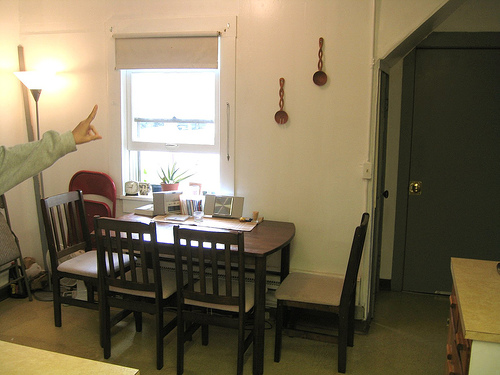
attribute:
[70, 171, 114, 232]
chair — folding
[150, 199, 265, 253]
table top — cluttered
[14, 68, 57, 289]
lamp — lit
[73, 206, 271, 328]
chairs — wood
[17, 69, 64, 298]
lamp — lit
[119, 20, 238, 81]
shade — white, glass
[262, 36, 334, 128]
spoons — hanging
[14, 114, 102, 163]
person — pointing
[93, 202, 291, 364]
table — wooden